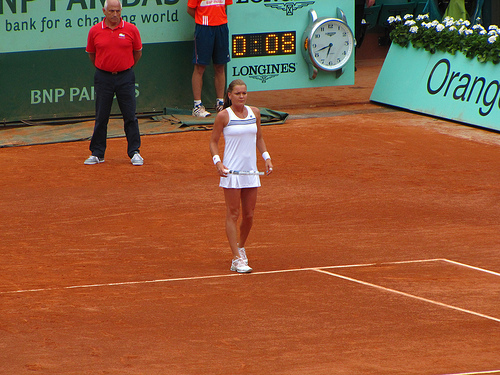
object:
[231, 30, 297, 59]
clock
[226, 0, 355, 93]
wall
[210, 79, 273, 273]
woman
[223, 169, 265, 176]
racket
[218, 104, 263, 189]
dress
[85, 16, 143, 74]
shirt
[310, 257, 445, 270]
line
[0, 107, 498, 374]
tennis court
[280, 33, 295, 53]
number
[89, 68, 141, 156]
pants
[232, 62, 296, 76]
writing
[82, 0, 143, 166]
man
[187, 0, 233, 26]
shirt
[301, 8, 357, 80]
analog clock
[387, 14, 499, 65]
flowers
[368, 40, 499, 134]
wall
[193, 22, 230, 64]
shorts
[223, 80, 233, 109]
ponytail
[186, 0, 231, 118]
person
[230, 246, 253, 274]
shoes